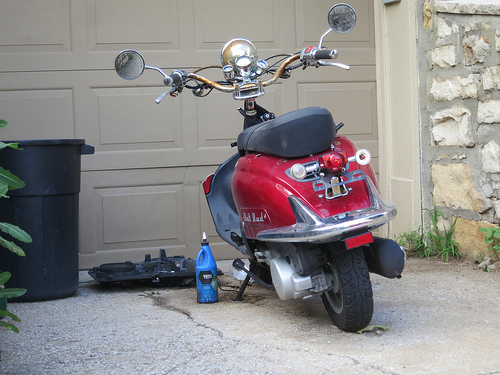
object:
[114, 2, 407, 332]
motorcycle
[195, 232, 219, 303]
bottle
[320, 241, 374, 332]
tire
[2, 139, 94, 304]
trash can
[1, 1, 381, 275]
garage door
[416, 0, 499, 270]
wall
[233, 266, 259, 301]
kickstand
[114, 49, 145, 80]
left rearview mirror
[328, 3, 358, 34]
right rearview mirro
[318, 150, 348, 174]
taillight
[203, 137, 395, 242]
body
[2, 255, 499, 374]
ground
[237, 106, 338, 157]
seat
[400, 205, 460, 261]
grass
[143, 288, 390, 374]
crack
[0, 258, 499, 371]
concrete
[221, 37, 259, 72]
head lamp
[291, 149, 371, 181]
break lights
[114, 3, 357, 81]
rearview mirrors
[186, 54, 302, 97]
rust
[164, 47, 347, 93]
handles